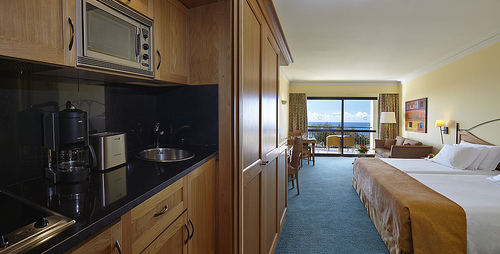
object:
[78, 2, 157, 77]
microwave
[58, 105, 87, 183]
coffee maker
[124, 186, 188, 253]
drawer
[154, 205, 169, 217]
handle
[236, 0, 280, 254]
closet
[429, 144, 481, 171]
pillows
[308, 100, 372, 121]
sky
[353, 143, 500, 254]
beds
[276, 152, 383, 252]
floor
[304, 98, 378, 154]
window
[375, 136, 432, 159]
sofa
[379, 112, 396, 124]
lamp shade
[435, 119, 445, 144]
wall lamp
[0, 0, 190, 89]
cabinet doors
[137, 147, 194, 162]
sink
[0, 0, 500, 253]
room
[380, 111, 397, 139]
lamp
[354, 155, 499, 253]
blanket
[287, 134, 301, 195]
chair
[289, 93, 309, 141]
curtains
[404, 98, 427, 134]
picture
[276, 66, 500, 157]
wall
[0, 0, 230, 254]
kitchen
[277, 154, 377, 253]
carpet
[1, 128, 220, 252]
counter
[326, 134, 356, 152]
bench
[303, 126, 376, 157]
balcony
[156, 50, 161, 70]
handle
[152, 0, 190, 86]
cabinet